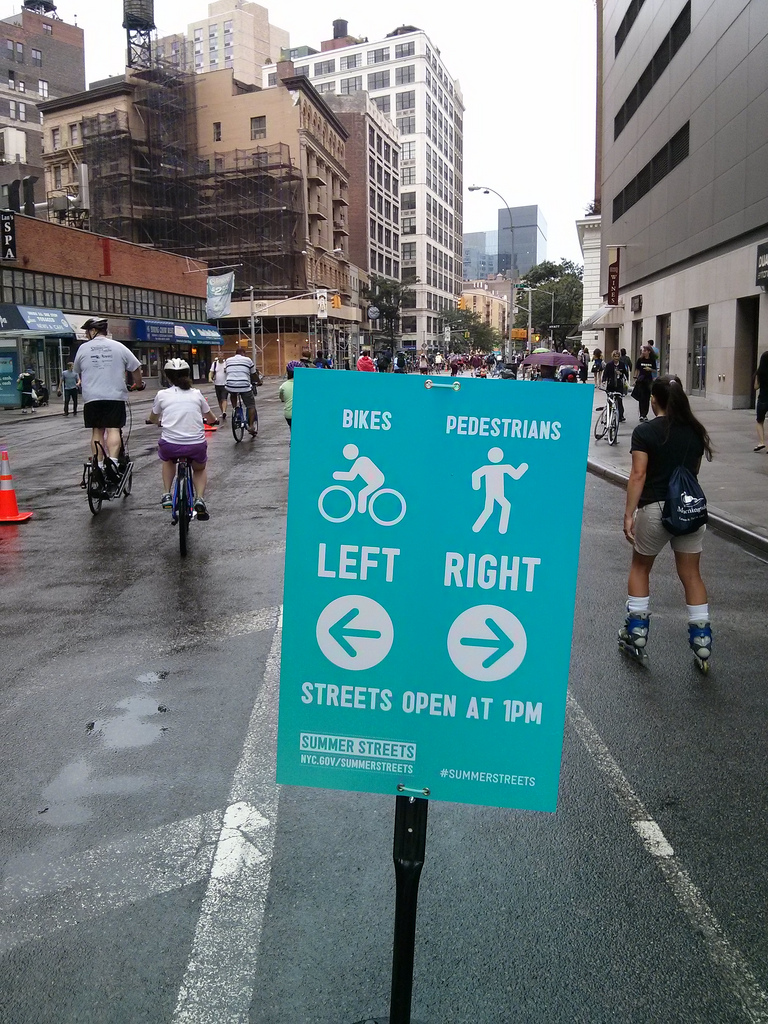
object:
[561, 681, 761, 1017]
line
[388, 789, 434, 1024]
pole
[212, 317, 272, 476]
people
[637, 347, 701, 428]
head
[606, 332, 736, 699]
girl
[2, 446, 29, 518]
cone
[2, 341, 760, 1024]
ground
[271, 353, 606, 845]
sign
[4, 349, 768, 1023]
street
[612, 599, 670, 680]
rollerblades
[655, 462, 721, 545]
bag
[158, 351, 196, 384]
helmet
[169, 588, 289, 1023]
line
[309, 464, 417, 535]
bicycle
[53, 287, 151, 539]
man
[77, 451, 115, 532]
cycle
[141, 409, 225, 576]
bicycle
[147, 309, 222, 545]
girl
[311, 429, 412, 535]
being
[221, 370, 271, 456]
bike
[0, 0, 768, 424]
building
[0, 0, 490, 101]
top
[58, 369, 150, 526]
bike